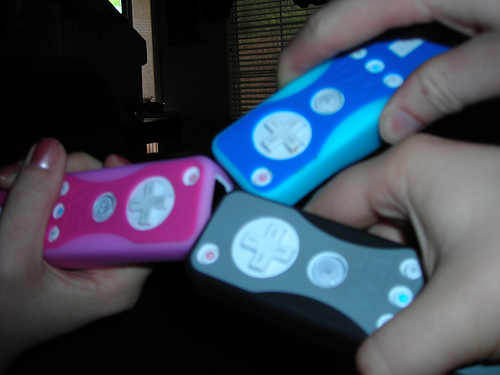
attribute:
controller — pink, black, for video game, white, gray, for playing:
[45, 162, 235, 264]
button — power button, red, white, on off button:
[185, 164, 202, 184]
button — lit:
[56, 178, 72, 193]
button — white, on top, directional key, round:
[129, 178, 175, 225]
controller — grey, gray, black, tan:
[190, 188, 430, 342]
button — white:
[376, 311, 395, 330]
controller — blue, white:
[203, 28, 449, 206]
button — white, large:
[250, 108, 310, 159]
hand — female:
[1, 138, 151, 368]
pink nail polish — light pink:
[31, 139, 62, 172]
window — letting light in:
[214, 2, 329, 144]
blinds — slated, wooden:
[230, 2, 311, 123]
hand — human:
[295, 135, 499, 374]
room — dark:
[3, 4, 496, 373]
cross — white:
[132, 182, 169, 223]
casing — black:
[189, 186, 423, 343]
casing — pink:
[40, 160, 240, 261]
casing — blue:
[213, 34, 469, 204]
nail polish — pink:
[114, 156, 131, 169]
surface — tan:
[190, 187, 422, 332]